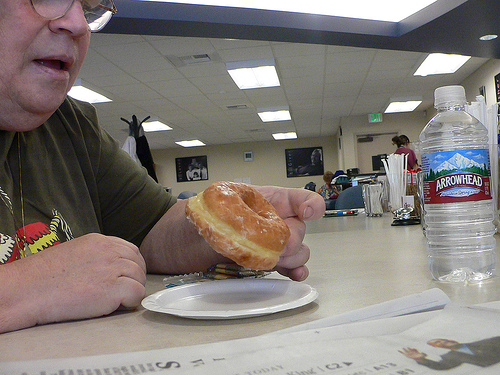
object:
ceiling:
[67, 0, 500, 151]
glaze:
[217, 187, 274, 242]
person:
[394, 335, 499, 370]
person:
[0, 0, 326, 333]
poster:
[281, 147, 327, 179]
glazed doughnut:
[184, 181, 292, 270]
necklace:
[0, 134, 33, 256]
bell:
[389, 207, 422, 225]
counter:
[0, 209, 499, 374]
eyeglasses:
[32, 1, 117, 34]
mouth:
[30, 54, 73, 79]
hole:
[238, 190, 270, 222]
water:
[419, 106, 497, 285]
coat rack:
[117, 112, 150, 160]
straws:
[379, 151, 411, 211]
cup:
[379, 172, 415, 214]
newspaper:
[0, 300, 499, 374]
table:
[0, 209, 499, 375]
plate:
[139, 276, 319, 321]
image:
[397, 336, 499, 372]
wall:
[128, 142, 338, 192]